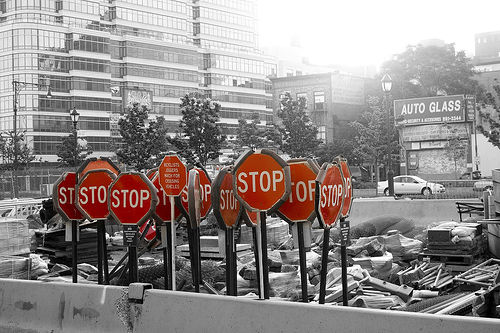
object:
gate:
[422, 177, 499, 204]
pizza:
[50, 149, 353, 232]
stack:
[419, 220, 485, 265]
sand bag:
[451, 225, 478, 243]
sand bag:
[436, 222, 459, 229]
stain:
[71, 304, 100, 321]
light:
[69, 109, 79, 124]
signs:
[73, 169, 117, 282]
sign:
[464, 96, 477, 123]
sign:
[313, 160, 345, 306]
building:
[269, 70, 394, 176]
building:
[393, 92, 500, 181]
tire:
[422, 187, 432, 196]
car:
[374, 175, 447, 196]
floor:
[351, 179, 499, 204]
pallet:
[0, 217, 37, 282]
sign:
[229, 147, 291, 300]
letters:
[237, 171, 282, 191]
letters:
[112, 190, 148, 208]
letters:
[322, 185, 342, 207]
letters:
[79, 185, 106, 204]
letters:
[59, 187, 74, 203]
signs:
[75, 155, 121, 286]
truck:
[457, 169, 495, 179]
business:
[391, 93, 474, 179]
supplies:
[0, 151, 499, 307]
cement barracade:
[0, 278, 499, 333]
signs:
[51, 172, 85, 284]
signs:
[106, 170, 157, 284]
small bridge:
[0, 203, 500, 333]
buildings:
[0, 0, 390, 186]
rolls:
[128, 255, 224, 297]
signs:
[157, 154, 187, 291]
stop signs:
[46, 150, 353, 229]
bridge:
[346, 177, 500, 217]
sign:
[330, 73, 366, 106]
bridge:
[0, 279, 500, 333]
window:
[37, 28, 67, 52]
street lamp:
[380, 72, 393, 91]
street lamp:
[67, 106, 79, 123]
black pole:
[386, 95, 394, 196]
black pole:
[72, 123, 77, 158]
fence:
[106, 254, 225, 288]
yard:
[0, 0, 497, 333]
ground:
[0, 181, 500, 333]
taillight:
[376, 180, 380, 190]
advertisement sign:
[392, 93, 468, 127]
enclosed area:
[0, 195, 500, 333]